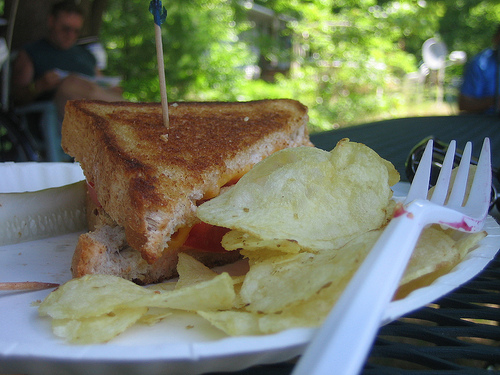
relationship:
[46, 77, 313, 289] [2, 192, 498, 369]
sandwich on plate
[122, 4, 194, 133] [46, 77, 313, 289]
toothpick on sandwich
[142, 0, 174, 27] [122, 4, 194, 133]
frill on toothpick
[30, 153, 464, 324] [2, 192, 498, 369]
potato chips on plate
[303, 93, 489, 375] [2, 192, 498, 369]
fork on plate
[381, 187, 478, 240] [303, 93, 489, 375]
food on fork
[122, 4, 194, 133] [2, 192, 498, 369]
toothpick on plate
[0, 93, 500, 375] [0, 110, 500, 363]
lunch on table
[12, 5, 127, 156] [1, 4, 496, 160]
man in background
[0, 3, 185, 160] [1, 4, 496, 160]
house in background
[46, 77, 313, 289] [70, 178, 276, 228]
sandwich has cheese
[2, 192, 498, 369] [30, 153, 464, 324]
plate has potato chips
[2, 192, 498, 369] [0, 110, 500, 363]
plate on table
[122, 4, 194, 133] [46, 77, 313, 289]
toothpick skewer holds sandwich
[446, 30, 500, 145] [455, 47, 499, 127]
man in shirt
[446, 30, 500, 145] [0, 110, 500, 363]
man sitting at table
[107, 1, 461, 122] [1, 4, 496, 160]
foliage in background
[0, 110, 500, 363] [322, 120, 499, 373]
table has design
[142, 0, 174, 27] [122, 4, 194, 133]
frill of skewer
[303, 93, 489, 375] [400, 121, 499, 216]
fork has prongs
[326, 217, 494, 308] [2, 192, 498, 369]
pickle of plate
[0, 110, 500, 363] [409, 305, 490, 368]
picic table has holes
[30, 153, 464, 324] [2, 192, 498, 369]
chips on plate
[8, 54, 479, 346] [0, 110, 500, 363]
lunch on picnic table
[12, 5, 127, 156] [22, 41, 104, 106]
man in shirt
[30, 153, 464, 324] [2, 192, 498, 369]
potato chips of plate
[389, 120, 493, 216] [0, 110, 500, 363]
sunglasses on table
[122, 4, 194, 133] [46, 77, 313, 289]
toothpick sticking out of sandwich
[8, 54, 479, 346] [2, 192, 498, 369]
lunch on plate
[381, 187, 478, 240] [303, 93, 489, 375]
sauce of fork